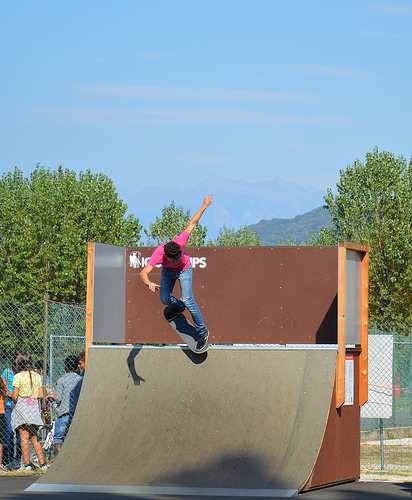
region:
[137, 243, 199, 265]
skaterboarder's shirt is pink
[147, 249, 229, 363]
skateboarder on the ramp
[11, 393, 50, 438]
jacket tried around her waist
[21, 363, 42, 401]
girl has a ponytail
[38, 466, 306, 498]
white line at the bottom of ramp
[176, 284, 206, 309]
hole in the skater's blue jeans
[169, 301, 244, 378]
skateboard is black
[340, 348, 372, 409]
sign on side of ramp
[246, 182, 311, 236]
hill behind the ramp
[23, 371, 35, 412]
girl's shirt is yellow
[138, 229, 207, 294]
the shirt is pink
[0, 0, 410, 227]
the sky is clear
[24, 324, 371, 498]
the ramp is brown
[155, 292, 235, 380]
the skateboard is black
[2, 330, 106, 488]
people standing behind the fence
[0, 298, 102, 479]
the fence is gray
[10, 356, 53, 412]
the shirt is yellow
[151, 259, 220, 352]
the person is wearing blue jeans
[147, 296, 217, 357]
the person's shoes are black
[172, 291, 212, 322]
the jeans have a hole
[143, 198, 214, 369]
The boy is skateboarding on the ramp.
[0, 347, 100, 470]
People standing by the gate.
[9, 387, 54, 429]
A girl has a jacket tied around her waist.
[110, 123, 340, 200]
The blue sky is clear.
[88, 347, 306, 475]
A paved skateboarding ramp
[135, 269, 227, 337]
The person is wearing blue jeans.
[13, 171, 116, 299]
Green trees by the fence.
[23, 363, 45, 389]
The girl has a long ponytail.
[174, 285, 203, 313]
The jeans have a tear in the knee.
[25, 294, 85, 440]
The ramp is surrounded by a gate.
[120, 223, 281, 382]
the man in pink shirt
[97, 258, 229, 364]
the man in pink shirt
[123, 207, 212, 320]
the man in pink shirt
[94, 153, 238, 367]
the man in pink shirt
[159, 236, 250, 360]
the man in pink shirt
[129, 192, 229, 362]
man wearing blue jeans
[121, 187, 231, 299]
man wearing short sleeved pink t shirt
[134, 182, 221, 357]
man performing trick on skateboard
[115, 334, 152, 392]
shadow of outstretched arm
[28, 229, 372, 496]
wooden and metal skateboard trick ramp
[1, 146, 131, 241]
green leaves on tree with blue sky in background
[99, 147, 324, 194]
blue sky with mountain in background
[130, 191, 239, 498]
man on skateboard about to pitch forward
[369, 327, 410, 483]
tall metal chainlink fence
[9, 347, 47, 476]
back of woman wearing yellow t shirt